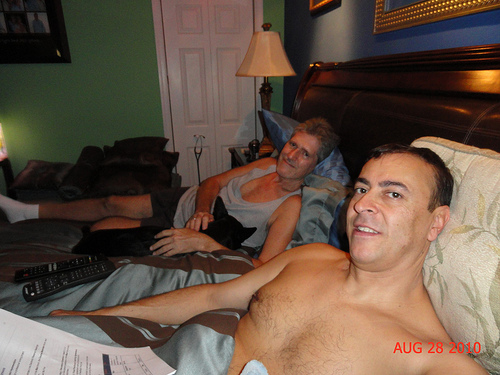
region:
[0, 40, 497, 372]
Two people are lying on a bed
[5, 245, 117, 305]
Two black remote controls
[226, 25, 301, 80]
A lampshade is white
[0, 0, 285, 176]
A wall is green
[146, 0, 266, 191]
A closed white door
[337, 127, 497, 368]
A man's head is on a pillow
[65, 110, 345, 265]
A man is holding a black dog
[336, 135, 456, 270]
The man is smiling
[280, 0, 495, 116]
A blue colored wall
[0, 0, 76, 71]
A photo frame is on the wall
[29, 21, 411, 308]
this is in a bedroom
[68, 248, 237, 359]
this is a bed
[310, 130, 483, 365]
this is a man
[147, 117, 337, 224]
this is a woman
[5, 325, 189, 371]
this is a piece of paper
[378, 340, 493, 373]
this is a timestamped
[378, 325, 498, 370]
the timestamp is red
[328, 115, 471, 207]
the man has brown hair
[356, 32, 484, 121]
the bed rest is brown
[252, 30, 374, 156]
this is a lamp shade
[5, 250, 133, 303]
Remote controls on the bed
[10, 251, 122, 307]
Remote controls are on the bed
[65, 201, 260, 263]
Dog on the bed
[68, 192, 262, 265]
Dog is on the bed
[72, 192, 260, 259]
Black dog on the bed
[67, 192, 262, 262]
Black dog is on the bed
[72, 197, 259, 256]
Dog laying on the bed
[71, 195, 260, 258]
Dog is laying on the bed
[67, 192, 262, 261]
Black dog laying on the bed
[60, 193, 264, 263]
Black dog is laying on the bed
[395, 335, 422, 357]
The word AUG in the date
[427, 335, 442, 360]
The numbers two and eight next to eachother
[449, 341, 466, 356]
The numbers two and zero next to each other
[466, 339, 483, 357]
The numbers one and zero next to each other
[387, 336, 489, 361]
The time stamp in the corner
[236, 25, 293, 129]
The lamp in the corner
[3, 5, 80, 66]
The picture on the green wall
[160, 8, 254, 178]
The white door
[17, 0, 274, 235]
The green wall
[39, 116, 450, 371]
Two people who are laying in bed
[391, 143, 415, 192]
This man has brown hair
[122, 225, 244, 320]
There is a dog pictured here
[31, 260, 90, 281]
There are two remote controls here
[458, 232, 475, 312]
There is a pillow visible here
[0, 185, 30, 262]
This man is wearing white socks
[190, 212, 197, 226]
This man is wearing a wedding ring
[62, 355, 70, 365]
This man has papers in front of him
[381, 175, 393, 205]
This man has rather thick eyebrows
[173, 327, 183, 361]
There is a silky comforter pictured here